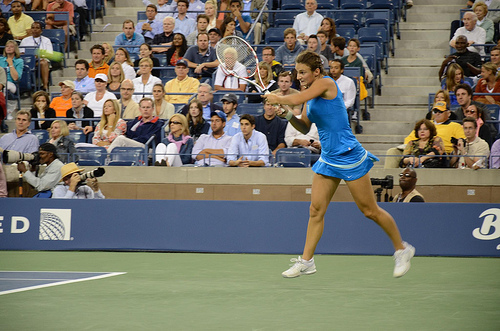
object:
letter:
[11, 216, 31, 234]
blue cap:
[210, 108, 225, 121]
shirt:
[50, 95, 75, 117]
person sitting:
[131, 57, 163, 102]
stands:
[0, 0, 500, 170]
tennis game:
[214, 35, 416, 280]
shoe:
[280, 257, 318, 279]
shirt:
[306, 76, 378, 182]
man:
[226, 114, 270, 169]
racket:
[215, 35, 285, 113]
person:
[450, 116, 488, 169]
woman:
[264, 51, 416, 279]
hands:
[261, 94, 280, 105]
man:
[189, 110, 233, 168]